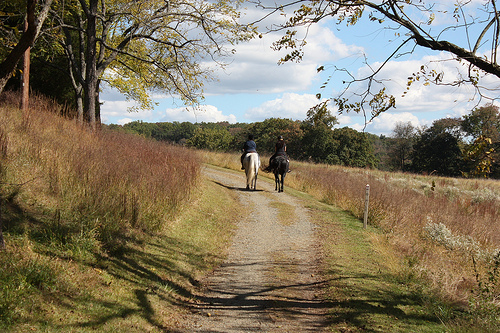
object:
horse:
[240, 150, 263, 191]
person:
[240, 133, 262, 162]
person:
[268, 132, 292, 157]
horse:
[266, 152, 293, 190]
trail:
[229, 196, 320, 333]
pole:
[362, 181, 379, 240]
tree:
[256, 2, 499, 125]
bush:
[121, 150, 200, 217]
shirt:
[244, 138, 260, 152]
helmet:
[246, 132, 255, 140]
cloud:
[303, 27, 356, 68]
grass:
[24, 223, 157, 273]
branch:
[336, 70, 380, 107]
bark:
[19, 47, 33, 110]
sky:
[349, 24, 379, 47]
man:
[273, 136, 291, 152]